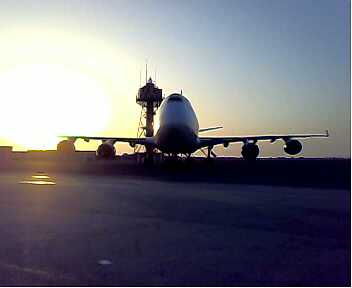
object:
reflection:
[15, 179, 51, 183]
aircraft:
[56, 93, 328, 163]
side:
[248, 89, 350, 123]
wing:
[198, 133, 331, 151]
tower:
[134, 63, 164, 168]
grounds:
[1, 172, 349, 287]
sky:
[0, 0, 349, 157]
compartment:
[155, 92, 195, 127]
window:
[167, 96, 182, 103]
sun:
[21, 119, 59, 153]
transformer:
[137, 82, 163, 108]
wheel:
[140, 153, 154, 169]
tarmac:
[2, 155, 351, 286]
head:
[158, 93, 194, 114]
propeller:
[284, 138, 302, 155]